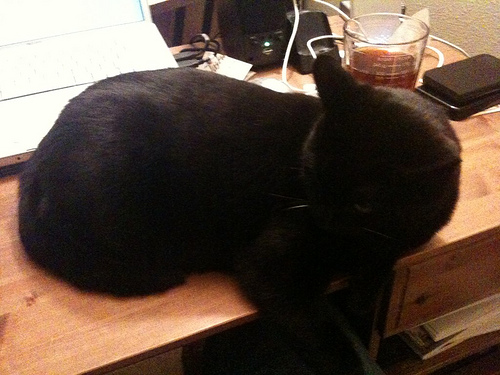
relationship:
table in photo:
[1, 256, 499, 363] [29, 17, 479, 355]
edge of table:
[95, 338, 235, 357] [1, 256, 499, 363]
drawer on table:
[399, 261, 499, 299] [1, 256, 499, 363]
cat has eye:
[27, 71, 462, 300] [348, 193, 382, 217]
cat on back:
[27, 71, 462, 300] [86, 84, 320, 187]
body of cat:
[71, 113, 260, 263] [27, 71, 462, 300]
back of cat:
[86, 84, 320, 187] [27, 71, 462, 300]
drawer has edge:
[399, 261, 499, 299] [385, 269, 410, 338]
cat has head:
[27, 71, 462, 300] [297, 112, 471, 240]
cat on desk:
[27, 71, 462, 300] [2, 230, 499, 345]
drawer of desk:
[399, 261, 499, 299] [2, 230, 499, 345]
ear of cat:
[298, 37, 353, 113] [27, 71, 462, 300]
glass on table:
[342, 16, 431, 87] [1, 256, 499, 363]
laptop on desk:
[9, 20, 158, 101] [2, 230, 499, 345]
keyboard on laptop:
[13, 48, 130, 78] [9, 20, 158, 101]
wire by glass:
[294, 10, 342, 68] [342, 16, 431, 87]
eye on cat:
[348, 193, 382, 217] [27, 71, 462, 300]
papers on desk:
[210, 48, 306, 99] [2, 230, 499, 345]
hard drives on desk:
[427, 56, 475, 110] [2, 230, 499, 345]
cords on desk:
[274, 4, 464, 63] [2, 230, 499, 345]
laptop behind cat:
[9, 20, 158, 101] [27, 71, 462, 300]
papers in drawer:
[428, 312, 499, 348] [399, 261, 499, 299]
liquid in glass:
[356, 55, 405, 83] [342, 16, 431, 87]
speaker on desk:
[237, 7, 290, 76] [2, 230, 499, 345]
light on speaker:
[259, 37, 271, 50] [237, 7, 290, 76]